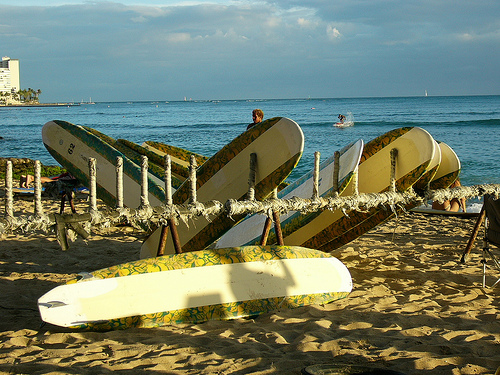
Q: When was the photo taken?
A: Daytime.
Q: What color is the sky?
A: Blue.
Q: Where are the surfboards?
A: On the beach.